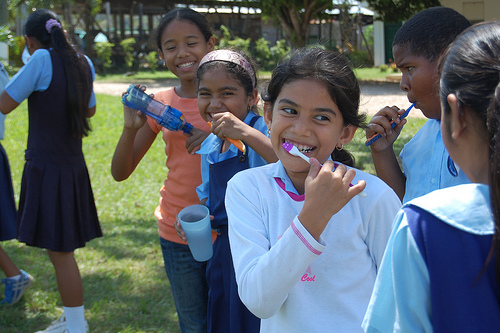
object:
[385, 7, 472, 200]
boy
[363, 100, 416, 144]
toothbrush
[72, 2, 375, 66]
fence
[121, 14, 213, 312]
girl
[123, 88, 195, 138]
bottle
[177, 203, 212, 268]
glass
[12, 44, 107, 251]
jumper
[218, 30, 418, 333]
child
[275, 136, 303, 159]
brush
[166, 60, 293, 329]
girl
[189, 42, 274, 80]
headband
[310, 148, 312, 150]
teeth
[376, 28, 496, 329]
girl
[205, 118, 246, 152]
toothbrush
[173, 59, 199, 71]
smile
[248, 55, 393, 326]
girl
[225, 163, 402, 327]
sweater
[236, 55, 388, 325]
kid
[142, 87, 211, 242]
shirt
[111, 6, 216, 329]
child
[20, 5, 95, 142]
hair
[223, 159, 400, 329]
shirt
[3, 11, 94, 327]
girl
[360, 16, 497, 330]
child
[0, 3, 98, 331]
kid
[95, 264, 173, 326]
grass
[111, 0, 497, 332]
children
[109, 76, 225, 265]
cups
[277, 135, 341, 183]
toothbrush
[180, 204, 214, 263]
cup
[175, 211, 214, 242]
hand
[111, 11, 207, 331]
kids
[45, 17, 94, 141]
ponytail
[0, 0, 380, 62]
bushes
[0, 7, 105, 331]
child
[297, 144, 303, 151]
teeth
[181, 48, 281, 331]
kid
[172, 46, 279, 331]
child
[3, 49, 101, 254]
school uniform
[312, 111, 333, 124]
eye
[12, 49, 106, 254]
dress